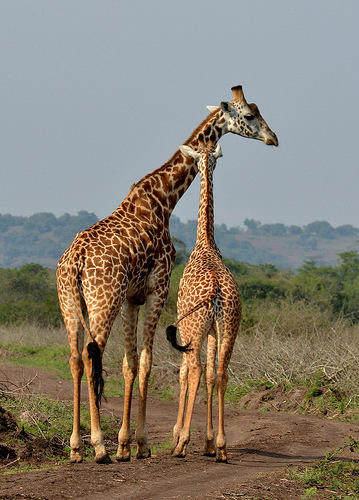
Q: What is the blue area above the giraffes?
A: Sky.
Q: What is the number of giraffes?
A: Two.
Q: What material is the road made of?
A: Dirt.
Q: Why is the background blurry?
A: Hazy sky.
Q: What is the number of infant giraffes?
A: One.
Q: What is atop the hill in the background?
A: Trees.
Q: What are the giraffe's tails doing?
A: Waving.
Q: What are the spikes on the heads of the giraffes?
A: Horns.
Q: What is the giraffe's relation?
A: Mom and baby.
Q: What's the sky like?
A: Blue.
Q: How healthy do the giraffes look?
A: Very healthy.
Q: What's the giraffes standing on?
A: Soil.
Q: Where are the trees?
A: Background.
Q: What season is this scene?
A: Summer.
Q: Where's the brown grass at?
A: In the middle.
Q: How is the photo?
A: Clear.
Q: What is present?
A: Animals.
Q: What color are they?
A: Brown.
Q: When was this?
A: Daytime.